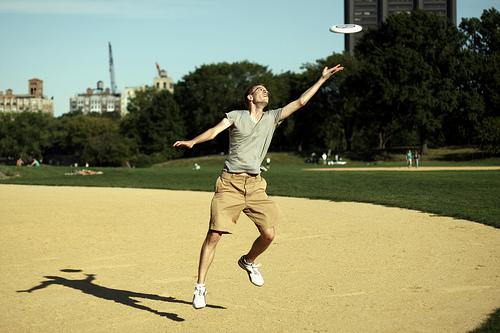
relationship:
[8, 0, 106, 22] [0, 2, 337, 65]
cloud floating in sky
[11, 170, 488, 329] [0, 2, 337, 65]
ground below sky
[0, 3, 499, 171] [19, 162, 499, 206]
trees are behind grass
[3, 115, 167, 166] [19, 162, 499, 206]
trees are behind grass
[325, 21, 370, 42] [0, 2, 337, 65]
frisbee flies in sky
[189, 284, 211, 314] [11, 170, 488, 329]
feet not touching ground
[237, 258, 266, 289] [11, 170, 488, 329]
feet not touching ground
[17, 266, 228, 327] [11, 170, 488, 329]
shadow on top of ground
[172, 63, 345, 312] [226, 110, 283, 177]
man wearing a shirt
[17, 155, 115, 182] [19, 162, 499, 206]
people siting on grass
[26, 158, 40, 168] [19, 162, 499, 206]
people siting on grass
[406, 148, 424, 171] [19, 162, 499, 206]
people are walking on grass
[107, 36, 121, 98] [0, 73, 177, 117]
cranes are behind buildings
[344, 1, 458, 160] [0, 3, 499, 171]
building behind trees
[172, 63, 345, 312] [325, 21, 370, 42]
man throwing a frisbee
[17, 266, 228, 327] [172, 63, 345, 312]
shadow below and left of man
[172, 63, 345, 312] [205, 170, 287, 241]
man wearing shorts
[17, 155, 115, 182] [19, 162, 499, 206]
people are sitting on grass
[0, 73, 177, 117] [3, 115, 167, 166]
buildings are behind trees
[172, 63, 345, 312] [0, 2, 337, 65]
man jumping into sky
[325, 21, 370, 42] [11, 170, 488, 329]
frisbee flying above ground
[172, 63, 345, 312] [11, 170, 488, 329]
man jumping away from ground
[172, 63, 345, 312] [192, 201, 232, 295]
man has a leg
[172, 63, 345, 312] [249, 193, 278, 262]
man has a leg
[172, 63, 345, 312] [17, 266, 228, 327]
man above and right o shadow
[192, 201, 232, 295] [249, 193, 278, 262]
leg to right of leg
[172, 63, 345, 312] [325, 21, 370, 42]
man catching a frisbee